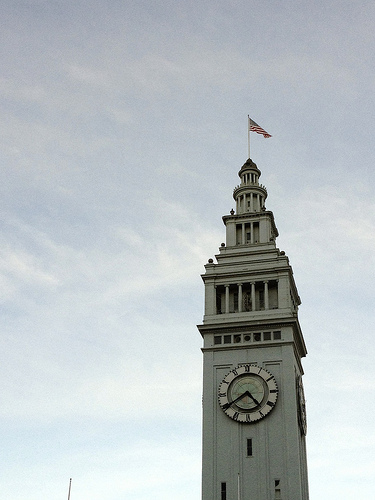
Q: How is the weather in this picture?
A: It is cloudy.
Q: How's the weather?
A: It is cloudy.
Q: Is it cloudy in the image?
A: Yes, it is cloudy.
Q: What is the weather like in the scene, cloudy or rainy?
A: It is cloudy.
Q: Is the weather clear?
A: No, it is cloudy.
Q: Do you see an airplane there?
A: No, there are no airplanes.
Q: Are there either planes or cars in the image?
A: No, there are no planes or cars.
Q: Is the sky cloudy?
A: Yes, the sky is cloudy.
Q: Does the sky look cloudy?
A: Yes, the sky is cloudy.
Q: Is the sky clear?
A: No, the sky is cloudy.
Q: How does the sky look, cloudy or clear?
A: The sky is cloudy.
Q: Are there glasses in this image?
A: No, there are no glasses.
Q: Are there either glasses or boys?
A: No, there are no glasses or boys.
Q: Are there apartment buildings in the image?
A: No, there are no apartment buildings.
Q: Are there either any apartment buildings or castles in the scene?
A: No, there are no apartment buildings or castles.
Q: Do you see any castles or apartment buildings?
A: No, there are no apartment buildings or castles.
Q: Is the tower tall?
A: Yes, the tower is tall.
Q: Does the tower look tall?
A: Yes, the tower is tall.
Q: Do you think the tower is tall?
A: Yes, the tower is tall.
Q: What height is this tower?
A: The tower is tall.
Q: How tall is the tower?
A: The tower is tall.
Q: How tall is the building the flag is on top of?
A: The tower is tall.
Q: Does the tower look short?
A: No, the tower is tall.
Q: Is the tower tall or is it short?
A: The tower is tall.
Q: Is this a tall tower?
A: Yes, this is a tall tower.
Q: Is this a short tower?
A: No, this is a tall tower.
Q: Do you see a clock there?
A: Yes, there is a clock.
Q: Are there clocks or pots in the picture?
A: Yes, there is a clock.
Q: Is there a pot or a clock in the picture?
A: Yes, there is a clock.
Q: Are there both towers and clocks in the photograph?
A: Yes, there are both a clock and a tower.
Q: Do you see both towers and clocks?
A: Yes, there are both a clock and a tower.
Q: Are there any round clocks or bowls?
A: Yes, there is a round clock.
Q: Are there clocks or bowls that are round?
A: Yes, the clock is round.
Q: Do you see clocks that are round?
A: Yes, there is a round clock.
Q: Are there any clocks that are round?
A: Yes, there is a clock that is round.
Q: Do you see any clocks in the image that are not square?
A: Yes, there is a round clock.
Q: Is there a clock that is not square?
A: Yes, there is a round clock.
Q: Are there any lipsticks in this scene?
A: No, there are no lipsticks.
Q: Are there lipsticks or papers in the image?
A: No, there are no lipsticks or papers.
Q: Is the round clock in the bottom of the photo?
A: Yes, the clock is in the bottom of the image.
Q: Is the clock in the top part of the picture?
A: No, the clock is in the bottom of the image.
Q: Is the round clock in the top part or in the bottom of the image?
A: The clock is in the bottom of the image.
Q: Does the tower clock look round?
A: Yes, the clock is round.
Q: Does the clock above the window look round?
A: Yes, the clock is round.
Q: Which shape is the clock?
A: The clock is round.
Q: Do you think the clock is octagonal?
A: No, the clock is round.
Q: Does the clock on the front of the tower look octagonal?
A: No, the clock is round.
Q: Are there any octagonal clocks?
A: No, there is a clock but it is round.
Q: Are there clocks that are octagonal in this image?
A: No, there is a clock but it is round.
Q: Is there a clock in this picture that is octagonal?
A: No, there is a clock but it is round.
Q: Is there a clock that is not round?
A: No, there is a clock but it is round.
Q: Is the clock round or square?
A: The clock is round.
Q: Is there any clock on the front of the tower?
A: Yes, there is a clock on the front of the tower.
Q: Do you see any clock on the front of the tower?
A: Yes, there is a clock on the front of the tower.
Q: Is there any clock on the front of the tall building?
A: Yes, there is a clock on the front of the tower.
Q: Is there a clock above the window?
A: Yes, there is a clock above the window.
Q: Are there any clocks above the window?
A: Yes, there is a clock above the window.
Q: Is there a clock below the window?
A: No, the clock is above the window.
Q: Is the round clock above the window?
A: Yes, the clock is above the window.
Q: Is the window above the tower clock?
A: No, the clock is above the window.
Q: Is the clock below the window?
A: No, the clock is above the window.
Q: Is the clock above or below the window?
A: The clock is above the window.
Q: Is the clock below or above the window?
A: The clock is above the window.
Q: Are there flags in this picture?
A: Yes, there is a flag.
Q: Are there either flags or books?
A: Yes, there is a flag.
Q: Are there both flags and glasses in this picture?
A: No, there is a flag but no glasses.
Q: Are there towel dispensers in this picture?
A: No, there are no towel dispensers.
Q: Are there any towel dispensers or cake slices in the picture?
A: No, there are no towel dispensers or cake slices.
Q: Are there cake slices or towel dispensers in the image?
A: No, there are no towel dispensers or cake slices.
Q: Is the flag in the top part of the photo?
A: Yes, the flag is in the top of the image.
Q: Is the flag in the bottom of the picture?
A: No, the flag is in the top of the image.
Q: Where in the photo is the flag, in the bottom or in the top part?
A: The flag is in the top of the image.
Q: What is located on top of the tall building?
A: The flag is on top of the tower.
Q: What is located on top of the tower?
A: The flag is on top of the tower.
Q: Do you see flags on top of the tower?
A: Yes, there is a flag on top of the tower.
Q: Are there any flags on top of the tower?
A: Yes, there is a flag on top of the tower.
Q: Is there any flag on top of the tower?
A: Yes, there is a flag on top of the tower.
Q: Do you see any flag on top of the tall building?
A: Yes, there is a flag on top of the tower.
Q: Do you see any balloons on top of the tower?
A: No, there is a flag on top of the tower.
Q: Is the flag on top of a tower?
A: Yes, the flag is on top of a tower.